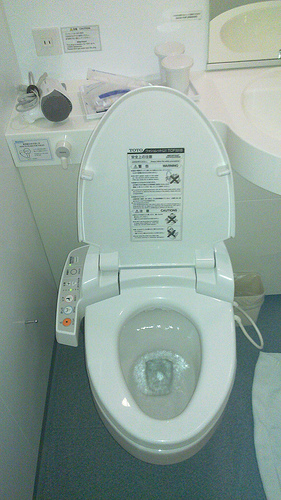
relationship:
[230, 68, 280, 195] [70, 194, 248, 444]
sink next to toilet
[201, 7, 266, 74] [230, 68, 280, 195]
mirror above sink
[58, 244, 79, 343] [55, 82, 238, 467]
side display on white toilet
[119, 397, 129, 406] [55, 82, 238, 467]
light falling on white toilet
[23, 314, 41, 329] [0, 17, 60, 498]
hanger on wall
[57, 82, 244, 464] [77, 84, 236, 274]
white toilet on toilet lid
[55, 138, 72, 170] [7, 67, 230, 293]
handle on tank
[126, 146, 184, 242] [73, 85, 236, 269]
display are printed on toilet lid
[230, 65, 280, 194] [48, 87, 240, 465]
sink next to toilet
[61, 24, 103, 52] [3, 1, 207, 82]
sign on wall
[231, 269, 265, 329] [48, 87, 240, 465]
trash can next to toilet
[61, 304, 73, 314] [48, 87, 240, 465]
button attached to toilet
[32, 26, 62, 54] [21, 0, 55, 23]
outlet on wall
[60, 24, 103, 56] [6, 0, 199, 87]
sign on wall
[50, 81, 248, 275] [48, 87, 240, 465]
toilet lid attached to toilet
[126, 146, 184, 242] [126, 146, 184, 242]
display of display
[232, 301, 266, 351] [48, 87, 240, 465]
tubing on side of toilet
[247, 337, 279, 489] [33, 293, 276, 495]
towel on floor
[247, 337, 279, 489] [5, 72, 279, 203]
towel in front of sink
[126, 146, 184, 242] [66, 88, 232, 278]
display on toilet lid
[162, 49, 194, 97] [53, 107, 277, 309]
container on toilet